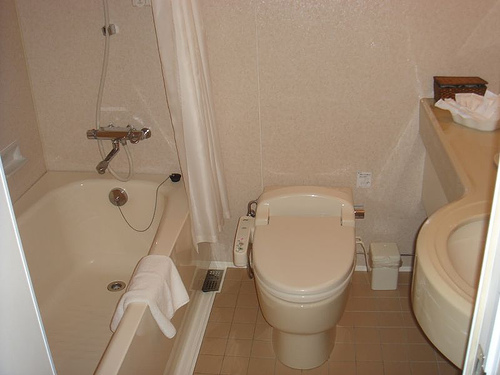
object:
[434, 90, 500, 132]
dispenser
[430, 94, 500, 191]
counter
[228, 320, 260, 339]
tile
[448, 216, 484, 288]
sink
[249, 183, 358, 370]
toilet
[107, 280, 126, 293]
drain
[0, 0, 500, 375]
bathroom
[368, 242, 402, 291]
trash can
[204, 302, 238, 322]
tile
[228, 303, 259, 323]
tile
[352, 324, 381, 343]
tile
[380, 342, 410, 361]
tile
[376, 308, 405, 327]
tile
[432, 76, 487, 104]
container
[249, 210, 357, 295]
lid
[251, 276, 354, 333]
bowl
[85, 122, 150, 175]
faucet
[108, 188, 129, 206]
drain control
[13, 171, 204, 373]
bathtub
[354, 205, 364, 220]
flush handle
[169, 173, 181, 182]
drain plug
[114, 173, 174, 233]
chain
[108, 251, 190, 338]
bath mat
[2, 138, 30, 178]
soap holder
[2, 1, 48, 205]
wall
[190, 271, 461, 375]
bathroom floor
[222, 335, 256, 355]
tile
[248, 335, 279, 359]
tile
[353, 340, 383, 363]
tile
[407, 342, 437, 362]
tile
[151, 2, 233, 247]
curtain